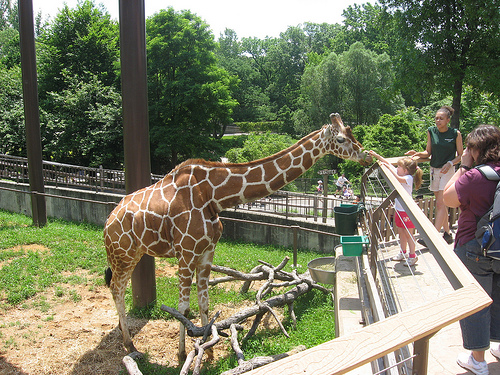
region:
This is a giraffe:
[39, 105, 370, 344]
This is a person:
[360, 139, 430, 296]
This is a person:
[417, 94, 465, 262]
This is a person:
[451, 107, 498, 370]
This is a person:
[389, 133, 417, 300]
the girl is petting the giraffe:
[91, 102, 458, 365]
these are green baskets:
[324, 189, 386, 288]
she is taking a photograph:
[437, 110, 499, 368]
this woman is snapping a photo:
[432, 98, 492, 373]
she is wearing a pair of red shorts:
[373, 144, 438, 272]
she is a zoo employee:
[405, 78, 486, 251]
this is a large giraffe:
[77, 85, 375, 370]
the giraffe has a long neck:
[66, 71, 391, 372]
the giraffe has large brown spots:
[75, 88, 380, 374]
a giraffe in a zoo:
[88, 21, 377, 373]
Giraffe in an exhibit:
[101, 108, 373, 359]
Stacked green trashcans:
[332, 200, 359, 235]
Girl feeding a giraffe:
[362, 146, 423, 269]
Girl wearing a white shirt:
[365, 147, 423, 268]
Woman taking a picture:
[441, 123, 498, 373]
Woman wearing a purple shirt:
[439, 120, 498, 373]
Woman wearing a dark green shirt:
[402, 98, 465, 248]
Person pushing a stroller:
[333, 170, 354, 202]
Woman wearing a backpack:
[443, 122, 498, 373]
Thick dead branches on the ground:
[120, 253, 335, 374]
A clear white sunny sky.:
[214, 1, 337, 16]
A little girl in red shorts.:
[364, 142, 425, 268]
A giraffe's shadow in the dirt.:
[74, 325, 155, 374]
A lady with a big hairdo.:
[434, 102, 455, 132]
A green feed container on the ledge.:
[340, 232, 369, 261]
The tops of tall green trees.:
[159, 1, 499, 96]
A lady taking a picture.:
[447, 123, 498, 373]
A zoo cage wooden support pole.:
[3, 0, 78, 255]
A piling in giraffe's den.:
[182, 251, 340, 373]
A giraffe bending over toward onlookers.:
[101, 109, 381, 354]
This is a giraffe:
[54, 70, 379, 362]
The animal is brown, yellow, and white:
[65, 80, 355, 366]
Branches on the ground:
[141, 228, 343, 368]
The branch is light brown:
[123, 230, 342, 372]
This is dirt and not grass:
[11, 284, 83, 371]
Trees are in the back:
[66, 6, 494, 217]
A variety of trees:
[36, 7, 489, 159]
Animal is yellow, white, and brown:
[36, 89, 343, 374]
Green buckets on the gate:
[298, 185, 384, 267]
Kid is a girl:
[356, 135, 433, 295]